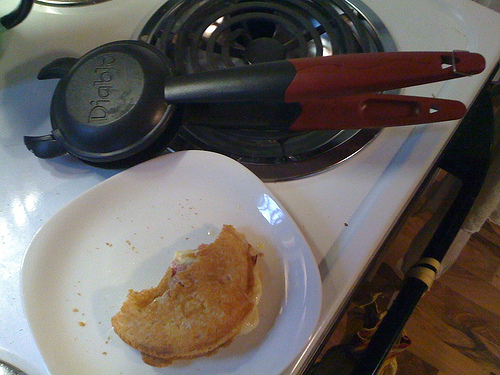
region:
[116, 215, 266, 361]
the sandwich is half eaten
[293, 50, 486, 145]
The handle is red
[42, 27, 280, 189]
The cooker is black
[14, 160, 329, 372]
The plate is square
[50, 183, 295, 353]
the plate is white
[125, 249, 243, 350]
the bread is brown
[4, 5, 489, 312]
the stove is white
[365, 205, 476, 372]
the handle is black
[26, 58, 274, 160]
the cooker is made of steel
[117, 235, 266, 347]
food is on the plate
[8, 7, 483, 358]
plate and cooking tool on top of stove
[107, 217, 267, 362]
letters on semicircle of partially eaten sandwich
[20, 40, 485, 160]
long red and black handle on circular pans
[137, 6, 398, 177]
round metal burner with black rings over surface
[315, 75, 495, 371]
towels hanging from black oven handle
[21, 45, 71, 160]
pointy and curved hinges on top of cooking tool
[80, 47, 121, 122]
letters over flat circular panel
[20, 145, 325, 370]
square plate with curved edges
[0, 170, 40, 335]
light reflecting off white surface of stove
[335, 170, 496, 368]
wooden floor of brown planks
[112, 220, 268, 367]
A sandwhich on a plate.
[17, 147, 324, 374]
A squarish white plate with rounded corners.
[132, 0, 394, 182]
A black burner on a stove.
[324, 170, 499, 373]
A wooden floor.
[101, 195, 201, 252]
Bread crumbs on a plate.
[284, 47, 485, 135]
Red handles on a stove tool.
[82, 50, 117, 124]
The word Diablo in black.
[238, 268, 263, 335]
Filling spilling out of a sandwich.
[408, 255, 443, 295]
A yellow cord wrapped around a pole.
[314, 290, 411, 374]
An object in the floor.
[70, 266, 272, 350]
a half eaten breakfast sandwich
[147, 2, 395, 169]
a burner on a stove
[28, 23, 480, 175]
diablo cooking apparatus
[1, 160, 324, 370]
square, white plate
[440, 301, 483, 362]
wooden kitchen floor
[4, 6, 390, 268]
top of an electric stove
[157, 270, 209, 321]
brand marking on sandwich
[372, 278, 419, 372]
dish towel handing from oven handle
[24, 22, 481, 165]
a diablo kitchen utensil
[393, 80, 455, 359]
handle of an oven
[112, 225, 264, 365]
Half eaten pancake on a plate.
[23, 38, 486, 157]
Black and red pancake mold.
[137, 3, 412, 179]
Black stove electric coil.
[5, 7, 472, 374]
Messy stove cooktop.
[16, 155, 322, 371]
White rectangle plate.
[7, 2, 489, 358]
White stove with black electric coils.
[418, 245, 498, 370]
Wood floor in the kitchen.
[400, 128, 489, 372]
Handle to open and close the oven.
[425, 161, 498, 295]
Napkin hanging on oven handle.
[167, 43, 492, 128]
Black and red pancake pan handle.